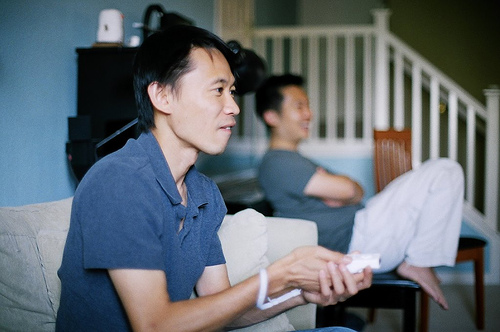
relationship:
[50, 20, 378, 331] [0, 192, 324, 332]
man sitting on couch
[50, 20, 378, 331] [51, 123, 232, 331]
man in shirt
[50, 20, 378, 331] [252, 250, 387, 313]
man holding controller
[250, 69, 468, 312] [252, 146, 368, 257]
man wearing shirt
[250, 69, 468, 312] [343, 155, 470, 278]
man wearing pants